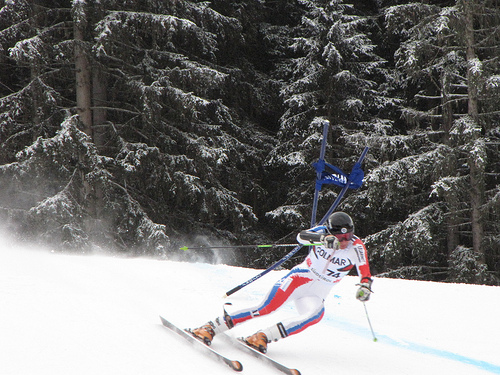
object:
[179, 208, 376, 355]
man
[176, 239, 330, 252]
ski poles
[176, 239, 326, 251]
ski pole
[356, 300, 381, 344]
ski pole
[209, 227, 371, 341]
outfit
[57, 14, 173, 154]
trunk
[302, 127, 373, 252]
ski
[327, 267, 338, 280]
number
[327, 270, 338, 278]
text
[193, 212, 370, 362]
man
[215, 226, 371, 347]
clothing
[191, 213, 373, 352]
person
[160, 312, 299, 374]
skis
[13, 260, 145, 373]
snow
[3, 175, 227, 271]
powder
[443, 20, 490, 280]
douglas fir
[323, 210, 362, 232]
helmet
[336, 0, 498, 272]
tree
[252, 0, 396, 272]
tree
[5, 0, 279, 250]
tree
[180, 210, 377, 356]
person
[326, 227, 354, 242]
goggles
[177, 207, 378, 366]
skier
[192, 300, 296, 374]
board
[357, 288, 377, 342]
ski poles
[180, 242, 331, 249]
ski poles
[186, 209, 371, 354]
skier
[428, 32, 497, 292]
trunk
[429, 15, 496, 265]
right